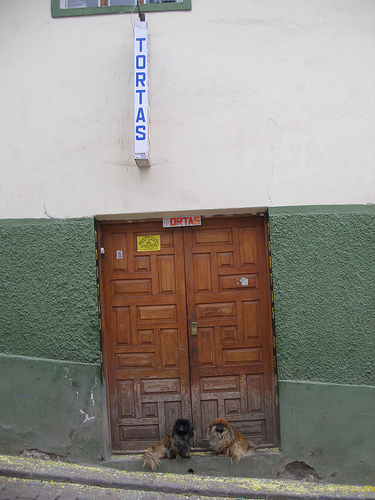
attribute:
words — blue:
[134, 36, 146, 139]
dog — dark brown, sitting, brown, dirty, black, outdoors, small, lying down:
[206, 414, 258, 465]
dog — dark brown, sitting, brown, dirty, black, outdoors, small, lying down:
[139, 415, 199, 472]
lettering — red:
[168, 216, 203, 228]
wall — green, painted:
[1, 209, 374, 485]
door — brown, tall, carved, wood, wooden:
[97, 215, 193, 457]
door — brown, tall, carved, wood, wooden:
[181, 213, 281, 450]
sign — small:
[161, 213, 203, 231]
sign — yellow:
[136, 234, 163, 252]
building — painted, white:
[0, 1, 375, 223]